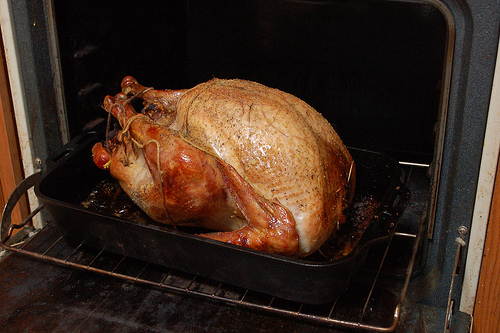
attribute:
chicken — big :
[91, 75, 356, 260]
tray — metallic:
[59, 181, 134, 243]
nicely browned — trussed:
[86, 71, 320, 225]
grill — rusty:
[24, 227, 46, 249]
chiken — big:
[107, 52, 361, 242]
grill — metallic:
[0, 212, 425, 332]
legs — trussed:
[100, 92, 225, 224]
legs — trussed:
[117, 75, 190, 120]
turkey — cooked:
[92, 74, 360, 259]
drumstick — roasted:
[99, 91, 225, 226]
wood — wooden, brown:
[464, 149, 498, 330]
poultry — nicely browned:
[88, 72, 360, 253]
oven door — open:
[2, 226, 474, 330]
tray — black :
[92, 187, 340, 276]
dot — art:
[286, 192, 296, 201]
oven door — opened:
[3, 1, 490, 331]